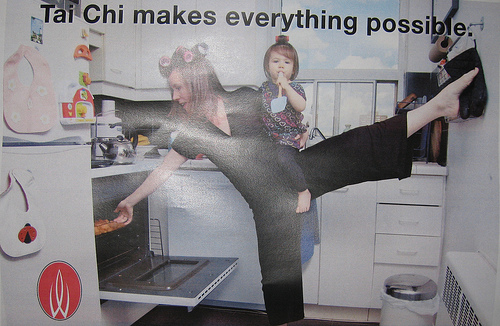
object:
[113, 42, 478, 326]
woman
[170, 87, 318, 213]
shirt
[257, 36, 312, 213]
child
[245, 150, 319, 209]
woman's hip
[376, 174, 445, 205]
cabinet drawer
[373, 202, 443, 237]
cabinet drawer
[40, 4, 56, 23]
letter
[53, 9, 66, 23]
letter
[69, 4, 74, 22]
letter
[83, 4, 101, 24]
letter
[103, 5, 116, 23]
letter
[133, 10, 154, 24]
letter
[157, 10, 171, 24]
letter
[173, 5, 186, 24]
letter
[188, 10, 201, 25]
letter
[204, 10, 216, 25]
letter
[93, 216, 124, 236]
food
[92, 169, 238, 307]
oven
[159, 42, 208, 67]
curlers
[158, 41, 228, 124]
woman's hair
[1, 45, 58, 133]
bib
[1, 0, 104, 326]
fridge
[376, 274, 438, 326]
trash can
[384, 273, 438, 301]
silver lid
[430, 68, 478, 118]
woman's foot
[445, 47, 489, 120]
oven mitt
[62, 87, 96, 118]
barn toy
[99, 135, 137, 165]
tea kettle